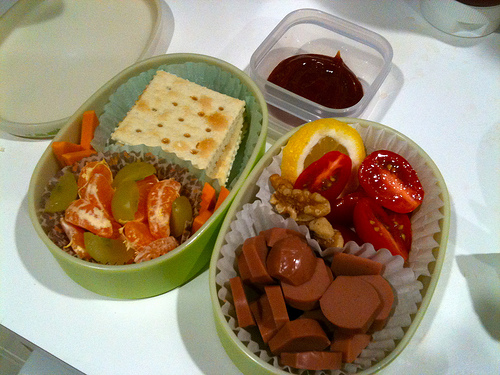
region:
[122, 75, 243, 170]
a stack of saltine crackers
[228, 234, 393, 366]
a muffin cup filled with sliced hot dogs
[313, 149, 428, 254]
sliced mini tomatoes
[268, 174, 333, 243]
walnuts in a cupcake tin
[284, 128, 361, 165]
a slice of yellow lemon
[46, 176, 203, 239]
a fruit salad made from oranges and green grapes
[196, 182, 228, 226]
three slivers of orange carrot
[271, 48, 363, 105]
a plastic container of ketchup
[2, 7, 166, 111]
the white lid of a plastic container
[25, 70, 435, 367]
two plastic containers filled with food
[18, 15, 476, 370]
Two containers of food.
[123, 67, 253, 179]
A stack of saltine crackers.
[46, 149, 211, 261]
Orange sections in bowl on left.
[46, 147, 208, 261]
Green grapes in bowl on left.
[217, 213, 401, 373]
A hot dog cut into bite size pieces.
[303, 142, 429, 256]
Cherry tomatoes cut up.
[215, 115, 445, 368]
Two white cupcake baking cups.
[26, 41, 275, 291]
A green oval shaped bowl.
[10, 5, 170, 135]
Oval lid for container.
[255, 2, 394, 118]
Small square container of sauce.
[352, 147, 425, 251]
cherry tomatoes cut in half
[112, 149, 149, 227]
green seedless grapes cut in half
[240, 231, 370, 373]
hot dogs cut in sliced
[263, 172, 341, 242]
walnuts in lunch tray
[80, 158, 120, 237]
orange sliced peeled and ready to eat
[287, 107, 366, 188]
lemon slice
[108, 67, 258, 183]
slatines with peanut butter on them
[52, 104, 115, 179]
carrot slices cut into triangles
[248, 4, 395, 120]
dipping sauce in plastic container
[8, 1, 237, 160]
gray lid to lunch plate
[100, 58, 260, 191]
Saltine crackers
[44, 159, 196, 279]
Fruit salad with grapes and oranges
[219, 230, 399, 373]
Hot dog slices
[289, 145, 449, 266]
Fresh tomato sections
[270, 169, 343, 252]
Some walnuts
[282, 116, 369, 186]
A slice of lemon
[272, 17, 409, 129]
Some dipping sauce in a cup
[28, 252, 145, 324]
The edge of a green ramekin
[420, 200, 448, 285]
Fluted paper holding food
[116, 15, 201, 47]
The edge of a container lid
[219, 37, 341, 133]
Catsup in a container.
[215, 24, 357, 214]
Catsup in a container.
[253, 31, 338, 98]
Catsup in a container.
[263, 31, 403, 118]
Catsup in a container.